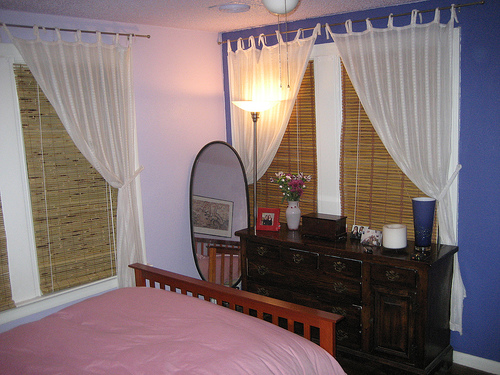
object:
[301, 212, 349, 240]
box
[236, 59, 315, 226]
blind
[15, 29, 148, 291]
curtain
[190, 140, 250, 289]
mirror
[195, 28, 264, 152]
corner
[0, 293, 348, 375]
comforter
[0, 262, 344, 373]
bed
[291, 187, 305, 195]
flower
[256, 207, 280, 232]
frame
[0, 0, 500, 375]
housing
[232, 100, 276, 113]
lamp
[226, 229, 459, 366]
dresser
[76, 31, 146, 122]
drape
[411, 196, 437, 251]
cup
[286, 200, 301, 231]
vase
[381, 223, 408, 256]
candle